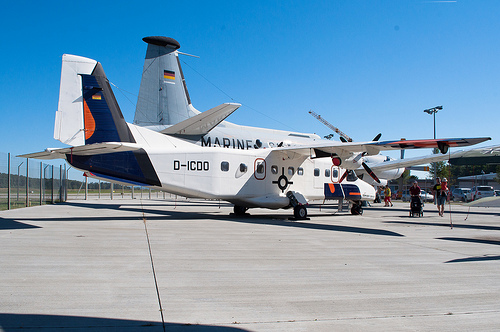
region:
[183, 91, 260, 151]
wing of a plane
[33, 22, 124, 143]
wing of a plane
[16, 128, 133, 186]
wing of a plane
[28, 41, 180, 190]
tail of a plane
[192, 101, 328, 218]
body of a plane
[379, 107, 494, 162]
wing of a plane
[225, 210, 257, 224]
wheel of a plane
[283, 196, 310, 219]
wheel of a plane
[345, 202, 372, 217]
wheel of a plane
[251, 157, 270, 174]
window of a plane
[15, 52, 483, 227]
airplane on the ground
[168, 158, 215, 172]
letters on the side of the airplane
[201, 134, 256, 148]
the word marine on the side of the plane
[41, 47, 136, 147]
tail of the airplane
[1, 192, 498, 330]
concrete material on the ground of the airport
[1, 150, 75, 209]
fencing behind the planes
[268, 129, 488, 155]
the rigt wing of a plane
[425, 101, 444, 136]
lamp post on the ground of the airport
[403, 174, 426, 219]
woman pushing a stroller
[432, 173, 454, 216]
man walking holding a child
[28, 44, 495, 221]
large white airplane sitting in a parking lot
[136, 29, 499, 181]
large gray marine plane sitting in a parking lot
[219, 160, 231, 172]
passenger window on the white plane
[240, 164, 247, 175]
passenger window on the white plane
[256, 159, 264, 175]
passenger window on the white plane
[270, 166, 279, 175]
passenger window on the white plane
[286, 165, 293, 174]
passenger window on the white plane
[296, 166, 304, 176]
passenger window on the white plane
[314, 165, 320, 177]
passenger window on the white plane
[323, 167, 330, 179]
passenger window on the white plane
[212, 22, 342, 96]
the sky is clear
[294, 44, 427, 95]
the sky is clear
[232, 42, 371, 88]
the sky is clear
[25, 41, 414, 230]
two planes on display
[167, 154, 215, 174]
figures on a white and blue plane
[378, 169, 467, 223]
people walking near a plane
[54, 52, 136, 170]
the tail of a big plane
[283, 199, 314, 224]
a wheel on a plane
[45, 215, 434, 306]
the ground under a plane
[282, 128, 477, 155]
the wing of a plane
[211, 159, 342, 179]
windows on a plane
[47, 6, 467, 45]
a very blues sky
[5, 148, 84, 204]
a fence around an area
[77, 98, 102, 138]
an orange spot on a plane